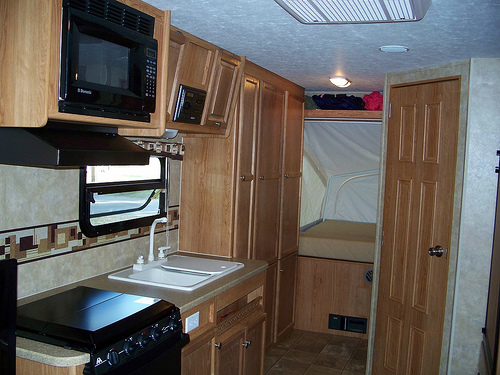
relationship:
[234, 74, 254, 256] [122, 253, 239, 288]
cabinet near sink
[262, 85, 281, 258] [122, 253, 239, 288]
cabinet near sink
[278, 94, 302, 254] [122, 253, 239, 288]
cabinet near sink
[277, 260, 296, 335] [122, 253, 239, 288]
cabinet near sink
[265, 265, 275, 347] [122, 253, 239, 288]
cabinet near sink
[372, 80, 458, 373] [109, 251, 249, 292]
brown door across sink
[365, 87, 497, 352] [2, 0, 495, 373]
door in kitchen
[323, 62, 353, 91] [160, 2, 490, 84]
light on ceiling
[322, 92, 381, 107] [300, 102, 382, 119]
clothes on shelf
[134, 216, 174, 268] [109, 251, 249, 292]
faucet on sink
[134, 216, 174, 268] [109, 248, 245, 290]
faucet above sink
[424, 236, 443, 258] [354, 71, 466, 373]
doorknob on door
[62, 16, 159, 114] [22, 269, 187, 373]
microwave above stove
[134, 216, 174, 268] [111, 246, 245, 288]
faucet on sink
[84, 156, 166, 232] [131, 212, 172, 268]
window behind faucet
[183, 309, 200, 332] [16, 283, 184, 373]
outlet next to dishwasher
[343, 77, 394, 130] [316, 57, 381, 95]
bag near light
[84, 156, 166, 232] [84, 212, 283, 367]
window above sink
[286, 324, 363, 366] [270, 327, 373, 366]
tile has on floor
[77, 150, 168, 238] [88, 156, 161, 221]
frame on window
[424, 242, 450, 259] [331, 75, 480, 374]
handle on door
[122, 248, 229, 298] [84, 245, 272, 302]
sink on counter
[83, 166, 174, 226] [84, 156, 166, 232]
cover on window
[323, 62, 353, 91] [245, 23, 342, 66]
light on ceiling